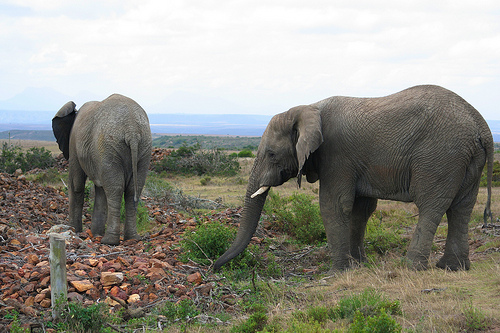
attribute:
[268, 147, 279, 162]
eye — elephant's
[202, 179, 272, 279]
trunk — long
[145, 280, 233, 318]
twigs — dead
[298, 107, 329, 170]
ear — elephant's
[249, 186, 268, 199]
tusk — white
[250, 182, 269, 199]
tusk — white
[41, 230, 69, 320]
post — wooden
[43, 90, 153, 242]
elephant — brown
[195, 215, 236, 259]
bush — small, green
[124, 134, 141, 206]
elephant's tail — short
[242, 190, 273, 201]
tuck — broken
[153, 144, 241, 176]
foilage — green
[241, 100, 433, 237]
elephant — grey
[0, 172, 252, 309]
rocks — red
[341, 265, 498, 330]
grass — green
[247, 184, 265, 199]
tusk — elephant's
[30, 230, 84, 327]
post — small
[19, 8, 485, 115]
sky — cloudy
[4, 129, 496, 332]
field — filled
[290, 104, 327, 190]
ear — elephant's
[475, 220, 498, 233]
pile — small